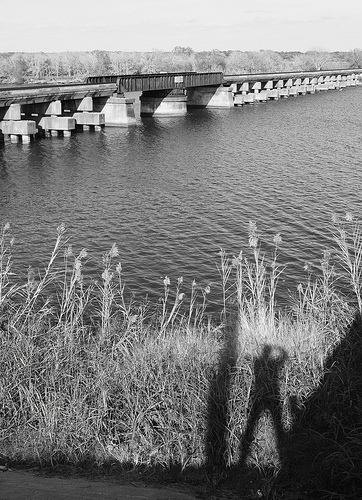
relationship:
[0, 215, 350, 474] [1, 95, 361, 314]
grass growing by water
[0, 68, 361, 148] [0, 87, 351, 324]
bridge over water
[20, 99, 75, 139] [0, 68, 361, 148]
support pylon for bridge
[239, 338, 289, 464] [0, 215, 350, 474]
shadow in grass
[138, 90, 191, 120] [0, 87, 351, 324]
pillar in water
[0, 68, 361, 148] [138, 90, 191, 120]
bridge has pillar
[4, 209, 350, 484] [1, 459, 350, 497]
plants next to road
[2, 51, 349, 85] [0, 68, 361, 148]
area on other side bridge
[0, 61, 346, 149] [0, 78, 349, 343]
bridge over water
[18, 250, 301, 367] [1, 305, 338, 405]
weeds near bank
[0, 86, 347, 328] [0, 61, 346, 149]
body over bridge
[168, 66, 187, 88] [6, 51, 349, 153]
sign on bridge